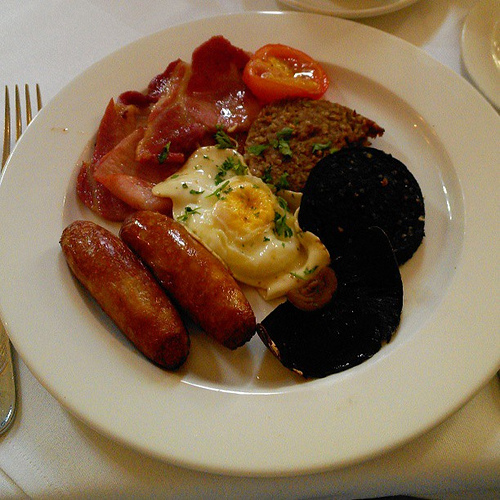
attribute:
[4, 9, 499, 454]
plate — white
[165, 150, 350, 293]
egg — yellow, white, fried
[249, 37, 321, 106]
tomato — red, sliced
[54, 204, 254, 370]
sausages — brown, cooked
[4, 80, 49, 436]
fork — silver